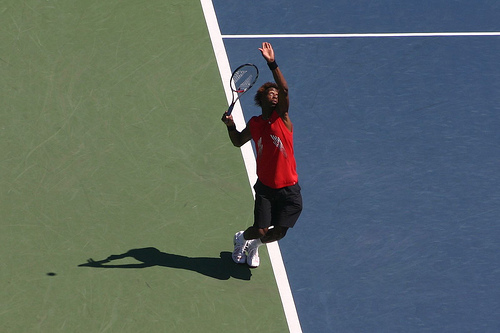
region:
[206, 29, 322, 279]
person ready to hit tennis ball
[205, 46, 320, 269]
person playing tennis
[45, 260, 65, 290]
shadow of tennis ball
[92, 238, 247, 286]
shadow of person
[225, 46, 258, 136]
person holding a tennis court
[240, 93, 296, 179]
person wearing a red shirt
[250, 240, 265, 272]
white shoe on left foot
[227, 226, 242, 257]
white shoe on right foot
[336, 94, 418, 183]
tennis court is blue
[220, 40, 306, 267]
a man swinging at a tennis ball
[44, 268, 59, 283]
the shadow of a tennis ball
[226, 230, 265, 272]
a man with white shoes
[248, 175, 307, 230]
a man with black shorts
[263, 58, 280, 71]
a man with a wristband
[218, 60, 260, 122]
a black and red racquet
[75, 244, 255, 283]
the shadow of a man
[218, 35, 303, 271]
a man swinging a tennis racquet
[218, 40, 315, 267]
a man jumping to swing a tennis racquet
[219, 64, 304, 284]
a black guy is playing tennis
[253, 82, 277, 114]
the head of a black guy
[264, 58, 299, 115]
the left arm of a black guy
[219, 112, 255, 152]
the right arm of a black guy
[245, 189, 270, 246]
the right leg of a black guy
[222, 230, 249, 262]
the right foot of a black guy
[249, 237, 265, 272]
the left foot of a black guy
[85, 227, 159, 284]
the shadow of a tennis player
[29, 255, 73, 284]
the shadow of a tennis ball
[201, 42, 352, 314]
Man in red shirt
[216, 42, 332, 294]
Man wearing black shorts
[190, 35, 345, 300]
Man wearing white shoes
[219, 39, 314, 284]
Man playing a game of tennis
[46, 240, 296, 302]
Shadow of the man playing tennis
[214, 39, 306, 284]
Man serving the tennis ball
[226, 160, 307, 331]
Man behind the fault line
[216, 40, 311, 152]
Man holding a tennis racket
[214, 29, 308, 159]
Man looking up at the tennis ball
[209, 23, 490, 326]
Man on a multi colored tennis court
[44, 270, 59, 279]
the shadow of the ball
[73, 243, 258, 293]
a shadow on the court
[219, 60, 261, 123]
a black tennis racket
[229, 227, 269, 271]
a pair of white tennis shoes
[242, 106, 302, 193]
a bright red tank top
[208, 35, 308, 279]
a man serving a tennis ball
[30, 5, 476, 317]
a blue and green tennis court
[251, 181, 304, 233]
a pair of black athletic shorts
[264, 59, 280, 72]
a soft black wristband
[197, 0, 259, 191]
a thick white line